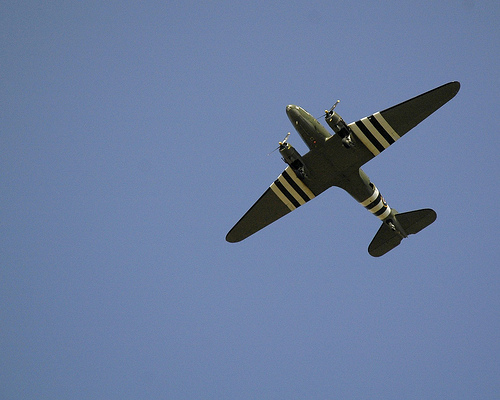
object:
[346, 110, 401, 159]
stripe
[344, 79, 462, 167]
wing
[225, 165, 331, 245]
wing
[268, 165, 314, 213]
stripe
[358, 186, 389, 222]
stripe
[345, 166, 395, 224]
body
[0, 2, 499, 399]
sky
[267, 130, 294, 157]
propeller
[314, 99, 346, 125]
propeller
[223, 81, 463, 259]
airplane